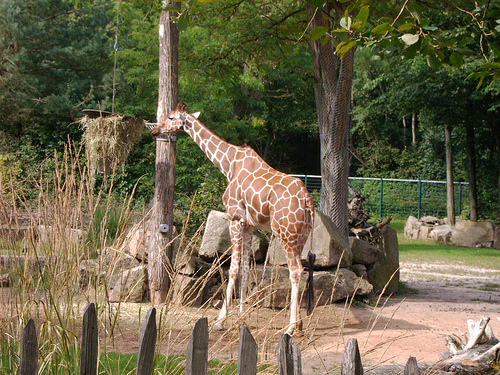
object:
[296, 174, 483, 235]
fence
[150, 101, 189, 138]
head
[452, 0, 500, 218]
tree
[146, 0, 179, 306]
pole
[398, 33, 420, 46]
leaf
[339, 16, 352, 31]
leaf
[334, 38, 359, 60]
leaf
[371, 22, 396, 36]
leaf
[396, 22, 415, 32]
leaf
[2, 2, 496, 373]
zoo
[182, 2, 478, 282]
tree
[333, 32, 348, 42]
leaf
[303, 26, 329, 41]
leaf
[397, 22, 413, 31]
leaf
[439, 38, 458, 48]
leaf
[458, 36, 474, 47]
leaf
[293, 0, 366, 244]
tree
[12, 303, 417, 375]
wooden fence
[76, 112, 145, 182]
hay bale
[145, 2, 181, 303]
tree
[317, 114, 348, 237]
trunk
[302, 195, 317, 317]
tail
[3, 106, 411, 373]
grass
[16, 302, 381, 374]
fence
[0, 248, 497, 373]
ground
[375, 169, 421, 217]
fence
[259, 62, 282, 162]
trees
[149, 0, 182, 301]
brown trunk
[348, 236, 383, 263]
stones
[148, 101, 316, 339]
giraffe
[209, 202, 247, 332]
legs